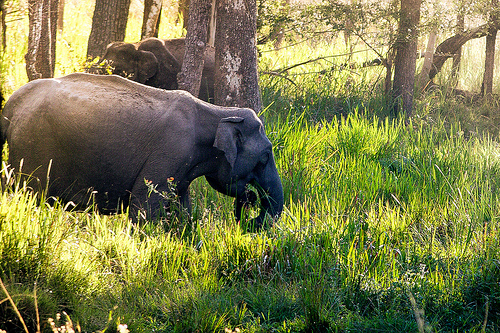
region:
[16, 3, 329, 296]
two elephants in the woods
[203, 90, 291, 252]
the head of a elephant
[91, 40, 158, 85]
the head of a elephant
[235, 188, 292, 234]
the trunk of a elephant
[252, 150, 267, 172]
the eye of a elephant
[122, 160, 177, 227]
the leg of a elephant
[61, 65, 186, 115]
the back of a elephant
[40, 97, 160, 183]
the skin of a elephant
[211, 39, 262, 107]
the trunk of a tree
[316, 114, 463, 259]
tall growing grass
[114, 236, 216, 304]
grass on the ground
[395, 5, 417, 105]
bark of the tree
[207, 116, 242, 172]
right ear on elephant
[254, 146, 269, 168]
right eye of the elephant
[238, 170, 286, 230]
the trunk of the elephant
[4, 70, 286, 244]
elephant in the grass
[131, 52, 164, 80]
left ear on the elephant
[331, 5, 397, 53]
branches on the tree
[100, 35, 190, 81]
elephant between the trees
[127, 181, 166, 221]
front leg of the elephant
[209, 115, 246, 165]
Floppy ears on an elephant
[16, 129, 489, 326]
Tall grass shaded by trees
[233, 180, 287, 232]
Curled trunk of an elephant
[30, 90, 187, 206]
Tough hide of an elephant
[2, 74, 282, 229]
An elephant walking through tall grass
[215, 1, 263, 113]
Trunk of a tree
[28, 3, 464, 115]
Trees casting shadows on a grassy field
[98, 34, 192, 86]
An elephant walking through trees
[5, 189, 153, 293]
Grass bathing in sunlight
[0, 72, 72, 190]
Backside of an elephant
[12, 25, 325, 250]
elephants in the grass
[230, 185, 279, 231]
trunk of the elephant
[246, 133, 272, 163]
eye of the elephant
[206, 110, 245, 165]
ear of the elephant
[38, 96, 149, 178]
the elephant is gray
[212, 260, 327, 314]
the grass is tall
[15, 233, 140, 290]
sun on the grass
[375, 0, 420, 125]
the tree is tall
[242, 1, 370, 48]
sparse leaves on trees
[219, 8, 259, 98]
the thick stem of a tree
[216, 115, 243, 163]
one ear of the elephant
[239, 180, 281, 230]
the elephant's trunk coiled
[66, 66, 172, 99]
the back of the elephant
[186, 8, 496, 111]
some trees in the background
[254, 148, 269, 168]
one eye of the elephant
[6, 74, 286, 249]
this elephant is eating grass